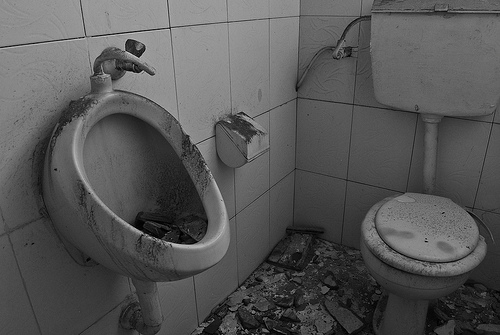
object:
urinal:
[41, 69, 230, 282]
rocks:
[174, 212, 208, 242]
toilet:
[361, 192, 487, 335]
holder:
[216, 111, 270, 169]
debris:
[434, 320, 456, 335]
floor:
[190, 225, 500, 335]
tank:
[369, 0, 499, 117]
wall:
[1, 0, 500, 335]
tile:
[0, 0, 499, 334]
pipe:
[119, 277, 163, 334]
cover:
[375, 193, 478, 263]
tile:
[189, 225, 500, 335]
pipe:
[421, 113, 444, 195]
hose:
[93, 47, 156, 76]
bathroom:
[0, 0, 500, 335]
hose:
[296, 15, 372, 87]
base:
[372, 286, 429, 334]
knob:
[125, 39, 146, 58]